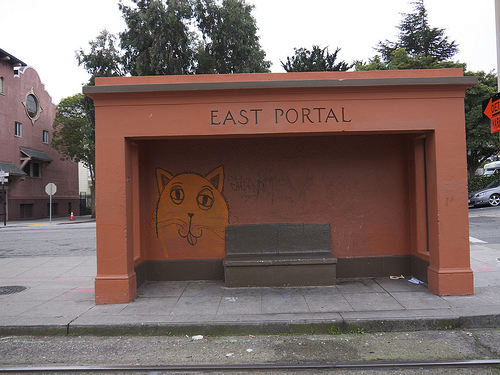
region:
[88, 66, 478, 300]
red and brown bus stop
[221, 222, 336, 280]
brown painted wood bench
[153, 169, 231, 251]
cat face on wall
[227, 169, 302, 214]
black graffiti on wall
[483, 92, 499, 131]
orange and black sign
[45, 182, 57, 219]
stop sign on post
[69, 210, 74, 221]
orange cone on sidewalk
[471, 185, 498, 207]
silver car on street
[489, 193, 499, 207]
black tire on car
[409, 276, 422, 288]
white paper on ground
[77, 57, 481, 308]
Brick shelter on the pavement.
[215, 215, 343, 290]
Bench in the shelter.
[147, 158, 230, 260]
Cat drawn on the wall.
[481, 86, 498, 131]
Sign by the shelter.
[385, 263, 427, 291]
Trash on the ground.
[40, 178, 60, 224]
Stop sign by the building.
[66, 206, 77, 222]
Orange cone by the building.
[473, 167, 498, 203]
Car on the street.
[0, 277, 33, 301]
Drain in the pavement.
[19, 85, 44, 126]
Circle window in the building.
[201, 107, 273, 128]
The words east.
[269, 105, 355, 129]
The word PORTAL.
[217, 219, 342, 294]
A brown bench.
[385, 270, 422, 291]
Trash in the corner.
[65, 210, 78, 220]
The orange cone on the street.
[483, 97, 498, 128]
Orange and black detour sign.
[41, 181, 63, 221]
The back of a stop sign.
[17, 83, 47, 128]
Circle shaped window.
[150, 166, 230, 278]
Cat picture painted on the wall.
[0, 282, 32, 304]
The pot hole on the ground.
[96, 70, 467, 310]
RED STRUCTURE AROUND BENCH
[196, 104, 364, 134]
EAST PORTAL ON STRUCTURE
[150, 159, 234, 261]
CAT DRAWN ON STRUCTURE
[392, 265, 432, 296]
DEBRIS SITTING ON SIDEWALK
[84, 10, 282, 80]
TREE GROWING AROUND STRUCTURE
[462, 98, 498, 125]
ORANGE SIGNS ON RIGHT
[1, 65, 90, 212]
RED BUILDING ON LEFT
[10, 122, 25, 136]
SMALL WINDOW ON BUILDING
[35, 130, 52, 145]
SMALL WINDOW ON BUILDING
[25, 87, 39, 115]
SMALL ROUND WINDOW ON BUILDING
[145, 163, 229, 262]
A cat painted on the wall.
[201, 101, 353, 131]
The words EAST PORTAL on the wall.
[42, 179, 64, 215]
The back of a street sign.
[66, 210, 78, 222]
The orange cone.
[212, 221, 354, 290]
The brown bench.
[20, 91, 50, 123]
The circle shaped window.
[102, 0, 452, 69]
The trees behind the bus stop.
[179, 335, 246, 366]
The trash on the street.